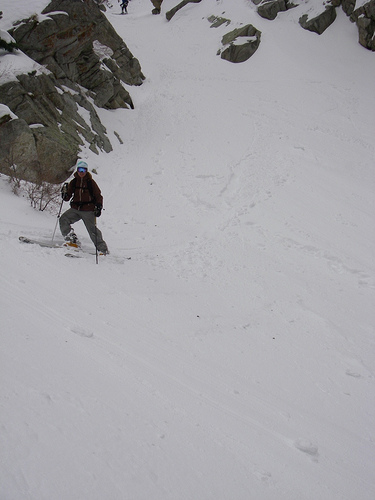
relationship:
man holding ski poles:
[58, 157, 109, 258] [88, 190, 100, 264]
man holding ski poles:
[58, 157, 109, 258] [49, 182, 67, 240]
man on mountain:
[59, 160, 109, 256] [2, 0, 373, 499]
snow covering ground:
[172, 86, 292, 207] [0, 76, 374, 498]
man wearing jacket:
[59, 160, 109, 256] [57, 170, 107, 215]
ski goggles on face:
[77, 166, 87, 172] [70, 164, 85, 178]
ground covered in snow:
[2, 2, 373, 497] [3, 2, 373, 499]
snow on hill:
[0, 0, 375, 500] [0, 0, 375, 260]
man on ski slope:
[59, 160, 109, 256] [1, 1, 373, 499]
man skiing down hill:
[59, 160, 109, 256] [170, 48, 313, 297]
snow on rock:
[0, 0, 375, 500] [247, 0, 303, 26]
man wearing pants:
[59, 160, 109, 256] [58, 207, 107, 250]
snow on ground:
[0, 0, 375, 500] [2, 2, 373, 497]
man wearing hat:
[58, 157, 109, 258] [71, 158, 89, 174]